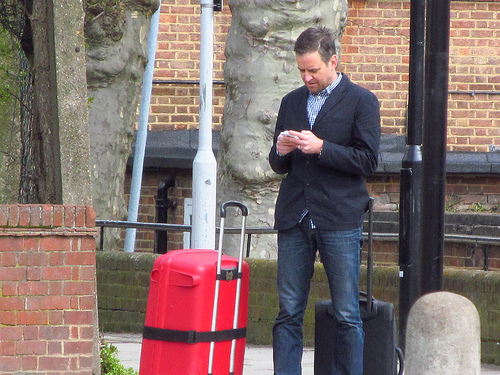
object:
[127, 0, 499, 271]
building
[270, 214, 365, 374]
blue jeans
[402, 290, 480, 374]
cement object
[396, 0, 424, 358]
metal pole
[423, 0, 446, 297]
metal pole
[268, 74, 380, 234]
jacket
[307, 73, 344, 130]
shirt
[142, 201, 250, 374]
suitcase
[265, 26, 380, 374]
man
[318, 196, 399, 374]
suitcase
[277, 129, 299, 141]
cellphone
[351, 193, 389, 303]
handle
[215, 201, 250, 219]
black handle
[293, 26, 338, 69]
brown hair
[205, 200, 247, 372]
metal handle